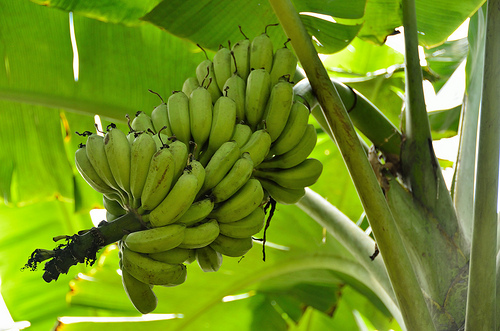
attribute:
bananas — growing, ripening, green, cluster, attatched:
[68, 25, 322, 320]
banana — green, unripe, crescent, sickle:
[122, 252, 186, 289]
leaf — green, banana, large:
[153, 2, 374, 66]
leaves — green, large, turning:
[57, 3, 467, 137]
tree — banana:
[267, 0, 497, 329]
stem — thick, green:
[28, 218, 139, 280]